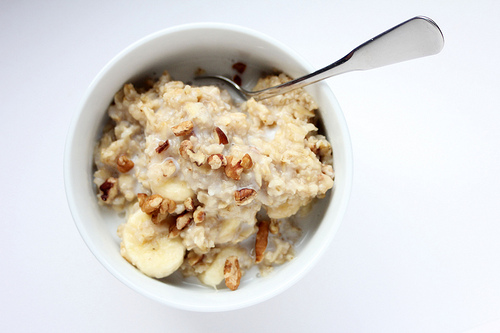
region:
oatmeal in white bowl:
[71, 0, 411, 320]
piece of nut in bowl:
[233, 185, 252, 206]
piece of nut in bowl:
[138, 200, 189, 225]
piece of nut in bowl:
[253, 230, 275, 262]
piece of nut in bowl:
[216, 130, 232, 154]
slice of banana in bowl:
[132, 227, 190, 284]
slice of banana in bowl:
[155, 161, 195, 202]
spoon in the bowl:
[190, 80, 337, 126]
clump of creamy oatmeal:
[268, 170, 311, 207]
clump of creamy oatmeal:
[121, 124, 170, 178]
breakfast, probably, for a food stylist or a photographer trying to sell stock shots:
[47, 8, 450, 324]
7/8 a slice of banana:
[115, 200, 187, 277]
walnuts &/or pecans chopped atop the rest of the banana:
[134, 194, 210, 232]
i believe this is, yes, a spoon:
[183, 9, 451, 116]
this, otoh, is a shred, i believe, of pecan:
[251, 211, 271, 266]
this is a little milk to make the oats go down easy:
[127, 107, 286, 204]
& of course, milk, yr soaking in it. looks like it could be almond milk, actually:
[86, 53, 335, 290]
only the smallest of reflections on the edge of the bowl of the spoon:
[208, 70, 240, 92]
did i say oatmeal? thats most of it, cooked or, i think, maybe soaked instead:
[102, 79, 335, 219]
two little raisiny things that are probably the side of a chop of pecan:
[223, 55, 250, 92]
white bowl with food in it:
[67, 7, 452, 292]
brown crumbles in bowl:
[105, 106, 288, 270]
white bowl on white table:
[6, 5, 456, 322]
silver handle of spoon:
[323, 15, 441, 71]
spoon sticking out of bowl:
[201, 22, 446, 102]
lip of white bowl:
[55, 27, 343, 317]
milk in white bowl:
[115, 82, 310, 273]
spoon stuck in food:
[70, 0, 435, 290]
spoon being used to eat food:
[184, 18, 456, 99]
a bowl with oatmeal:
[56, 15, 361, 320]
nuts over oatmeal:
[90, 62, 330, 288]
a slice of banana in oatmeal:
[113, 202, 191, 282]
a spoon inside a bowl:
[192, 10, 444, 105]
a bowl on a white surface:
[5, 5, 490, 325]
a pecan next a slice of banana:
[132, 185, 177, 230]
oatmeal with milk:
[93, 55, 330, 280]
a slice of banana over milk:
[108, 202, 195, 286]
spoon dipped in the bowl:
[177, 46, 282, 124]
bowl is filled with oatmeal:
[57, 15, 364, 320]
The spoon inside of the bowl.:
[200, 73, 265, 105]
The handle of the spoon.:
[255, 10, 445, 110]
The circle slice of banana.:
[120, 215, 180, 272]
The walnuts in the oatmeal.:
[131, 176, 271, 273]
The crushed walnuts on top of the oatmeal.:
[155, 95, 255, 185]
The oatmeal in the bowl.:
[105, 67, 330, 267]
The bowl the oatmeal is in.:
[67, 32, 362, 312]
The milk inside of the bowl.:
[107, 61, 302, 277]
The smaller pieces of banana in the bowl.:
[145, 161, 262, 280]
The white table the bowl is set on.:
[50, 17, 368, 332]